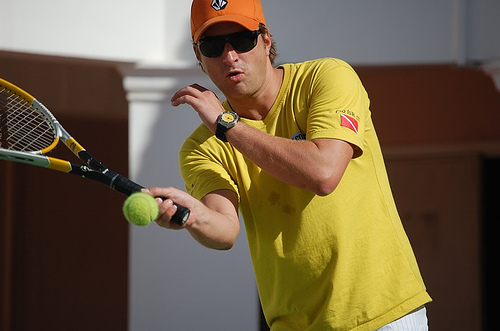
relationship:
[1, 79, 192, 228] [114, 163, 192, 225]
racket has handle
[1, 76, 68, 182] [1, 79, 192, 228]
head of racket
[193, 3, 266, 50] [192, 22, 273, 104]
cap on head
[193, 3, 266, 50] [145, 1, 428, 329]
cap on man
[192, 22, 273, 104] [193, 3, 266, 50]
head has cap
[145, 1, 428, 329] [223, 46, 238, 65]
man has nose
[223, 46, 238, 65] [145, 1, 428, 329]
nose of man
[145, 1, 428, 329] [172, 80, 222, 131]
man has hand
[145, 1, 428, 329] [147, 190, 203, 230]
man has hand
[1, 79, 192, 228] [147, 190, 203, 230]
racket in hand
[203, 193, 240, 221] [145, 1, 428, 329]
bicep of player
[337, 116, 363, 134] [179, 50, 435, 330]
logo on shirt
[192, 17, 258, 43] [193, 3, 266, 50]
front of cap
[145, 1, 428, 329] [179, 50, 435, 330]
man wears shirt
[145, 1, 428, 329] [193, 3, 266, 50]
man wears cap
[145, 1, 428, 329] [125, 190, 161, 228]
player kicks ball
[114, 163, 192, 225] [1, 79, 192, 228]
handle of racket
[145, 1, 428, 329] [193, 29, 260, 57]
man has sunglasses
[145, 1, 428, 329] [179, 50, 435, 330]
man wearing shirt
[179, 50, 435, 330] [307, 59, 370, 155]
shirt has sleeves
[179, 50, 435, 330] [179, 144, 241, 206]
shirt has sleeves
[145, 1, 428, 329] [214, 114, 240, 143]
man wearing watch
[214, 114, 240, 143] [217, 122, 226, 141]
watch has band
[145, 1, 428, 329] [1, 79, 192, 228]
man has racket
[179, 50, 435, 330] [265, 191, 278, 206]
shirt has spots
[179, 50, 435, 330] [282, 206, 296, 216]
shirt has spots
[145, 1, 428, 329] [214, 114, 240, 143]
man has wristwatch.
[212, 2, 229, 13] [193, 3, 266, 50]
emblem on cap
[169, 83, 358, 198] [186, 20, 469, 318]
arm of player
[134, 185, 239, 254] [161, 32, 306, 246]
arm of player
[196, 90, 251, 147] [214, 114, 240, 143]
watch on wrist